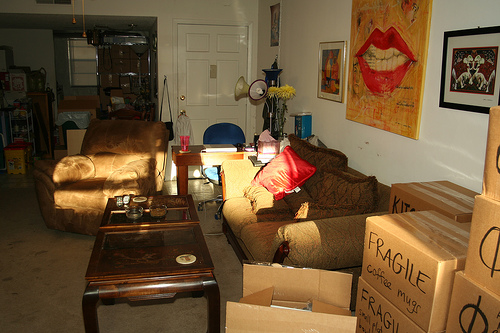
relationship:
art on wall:
[318, 40, 346, 103] [294, 20, 303, 73]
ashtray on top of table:
[150, 202, 167, 218] [105, 197, 162, 284]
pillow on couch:
[271, 148, 323, 198] [268, 139, 342, 259]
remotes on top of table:
[113, 191, 136, 211] [105, 197, 162, 284]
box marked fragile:
[225, 261, 358, 331] [366, 232, 436, 289]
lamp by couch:
[248, 81, 273, 132] [268, 139, 342, 259]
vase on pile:
[29, 63, 50, 93] [8, 51, 46, 178]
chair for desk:
[206, 124, 245, 146] [196, 127, 202, 173]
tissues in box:
[257, 137, 296, 156] [267, 139, 271, 155]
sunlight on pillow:
[267, 162, 295, 201] [271, 148, 323, 198]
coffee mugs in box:
[363, 263, 432, 317] [384, 223, 435, 282]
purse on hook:
[167, 87, 177, 148] [165, 72, 168, 89]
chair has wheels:
[206, 124, 245, 146] [197, 194, 225, 233]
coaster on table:
[165, 241, 204, 267] [105, 197, 162, 284]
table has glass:
[105, 197, 162, 284] [115, 209, 189, 220]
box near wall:
[225, 261, 358, 331] [432, 127, 480, 180]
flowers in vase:
[267, 79, 292, 104] [267, 108, 292, 137]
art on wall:
[439, 17, 500, 97] [432, 127, 480, 180]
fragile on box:
[354, 291, 397, 332] [355, 269, 381, 331]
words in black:
[363, 263, 432, 317] [369, 227, 376, 256]